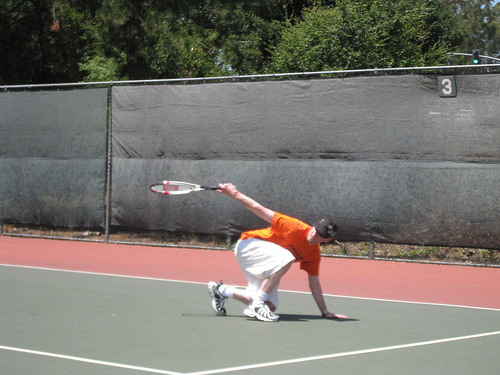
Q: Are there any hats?
A: Yes, there is a hat.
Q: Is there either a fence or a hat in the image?
A: Yes, there is a hat.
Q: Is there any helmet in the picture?
A: No, there are no helmets.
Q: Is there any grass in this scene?
A: Yes, there is grass.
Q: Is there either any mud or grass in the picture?
A: Yes, there is grass.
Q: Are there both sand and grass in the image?
A: No, there is grass but no sand.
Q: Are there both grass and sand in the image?
A: No, there is grass but no sand.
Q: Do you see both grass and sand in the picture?
A: No, there is grass but no sand.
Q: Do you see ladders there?
A: No, there are no ladders.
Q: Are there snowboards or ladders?
A: No, there are no ladders or snowboards.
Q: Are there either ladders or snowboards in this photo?
A: No, there are no ladders or snowboards.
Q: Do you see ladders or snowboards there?
A: No, there are no ladders or snowboards.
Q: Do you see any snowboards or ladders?
A: No, there are no ladders or snowboards.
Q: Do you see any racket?
A: Yes, there is a racket.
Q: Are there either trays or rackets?
A: Yes, there is a racket.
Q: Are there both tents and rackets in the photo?
A: No, there is a racket but no tents.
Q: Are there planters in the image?
A: No, there are no planters.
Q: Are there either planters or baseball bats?
A: No, there are no planters or baseball bats.